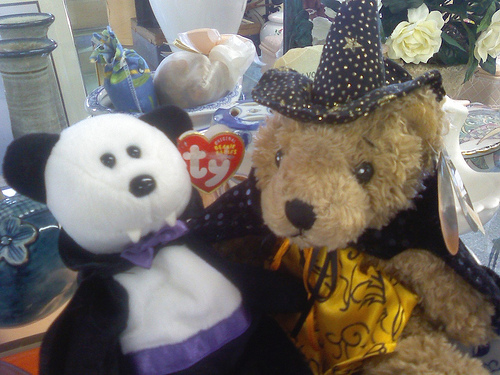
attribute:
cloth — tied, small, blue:
[308, 253, 419, 360]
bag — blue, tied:
[91, 41, 156, 108]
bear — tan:
[272, 91, 391, 264]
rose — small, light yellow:
[384, 1, 447, 63]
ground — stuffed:
[363, 178, 375, 189]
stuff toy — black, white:
[1, 101, 317, 373]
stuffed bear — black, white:
[1, 105, 321, 372]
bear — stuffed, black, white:
[9, 93, 292, 372]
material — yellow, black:
[263, 235, 423, 373]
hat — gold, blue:
[245, 0, 457, 133]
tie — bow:
[118, 218, 200, 268]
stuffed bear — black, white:
[10, 120, 238, 358]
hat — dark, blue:
[250, 1, 447, 125]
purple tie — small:
[100, 215, 271, 304]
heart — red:
[179, 131, 246, 194]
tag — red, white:
[173, 127, 246, 194]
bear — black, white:
[0, 105, 324, 374]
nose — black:
[285, 198, 315, 228]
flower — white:
[381, 5, 444, 65]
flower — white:
[463, 11, 484, 73]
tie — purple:
[116, 218, 186, 269]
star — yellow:
[324, 100, 350, 112]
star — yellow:
[341, 32, 361, 52]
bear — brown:
[187, 3, 485, 373]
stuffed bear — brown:
[242, 74, 484, 373]